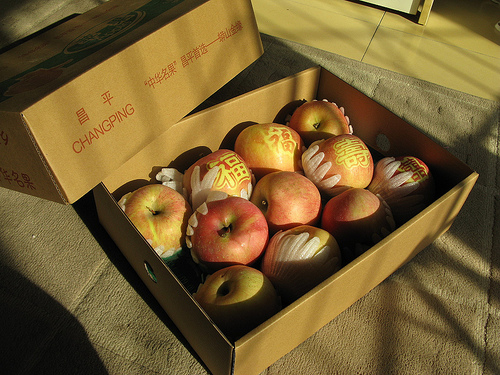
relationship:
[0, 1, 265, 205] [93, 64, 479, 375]
lid for box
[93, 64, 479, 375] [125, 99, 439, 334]
box with fruit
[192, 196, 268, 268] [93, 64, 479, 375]
apple in box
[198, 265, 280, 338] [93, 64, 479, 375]
apple in box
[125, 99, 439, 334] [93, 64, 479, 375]
fruit in box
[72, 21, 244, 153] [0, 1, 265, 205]
words on lid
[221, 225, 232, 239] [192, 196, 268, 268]
stem on apple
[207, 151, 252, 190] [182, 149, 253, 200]
lettering on apple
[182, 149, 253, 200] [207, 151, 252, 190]
apple has lettering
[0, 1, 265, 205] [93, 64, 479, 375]
lid on box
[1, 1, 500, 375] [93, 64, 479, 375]
rug under box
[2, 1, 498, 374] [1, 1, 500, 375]
shadows on rug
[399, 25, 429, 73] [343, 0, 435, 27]
reflection of furniture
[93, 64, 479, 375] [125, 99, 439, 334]
box holds fruit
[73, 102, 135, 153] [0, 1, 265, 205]
word on lid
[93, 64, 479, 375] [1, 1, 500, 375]
box on rug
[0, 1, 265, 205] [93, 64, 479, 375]
lid of box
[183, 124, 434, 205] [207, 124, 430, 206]
apples with lettering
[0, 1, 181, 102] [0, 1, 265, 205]
design on lid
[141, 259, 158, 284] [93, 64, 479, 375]
hole in box